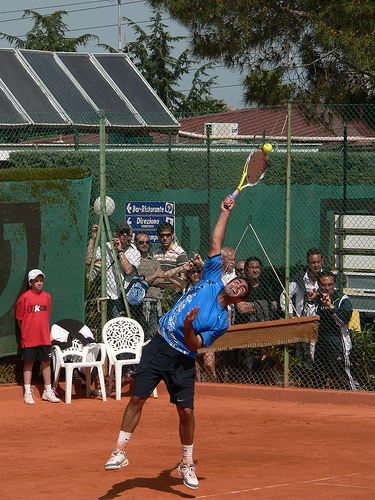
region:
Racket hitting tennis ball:
[257, 138, 277, 159]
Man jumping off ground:
[94, 429, 208, 499]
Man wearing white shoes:
[92, 434, 217, 490]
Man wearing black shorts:
[115, 326, 215, 416]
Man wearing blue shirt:
[154, 242, 236, 365]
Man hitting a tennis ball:
[149, 131, 284, 353]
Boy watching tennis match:
[14, 263, 71, 412]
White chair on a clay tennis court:
[98, 309, 166, 408]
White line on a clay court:
[268, 474, 330, 489]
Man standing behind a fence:
[300, 269, 358, 387]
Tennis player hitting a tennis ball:
[100, 139, 271, 486]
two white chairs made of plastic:
[45, 315, 153, 400]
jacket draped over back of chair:
[48, 315, 104, 401]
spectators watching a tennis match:
[85, 219, 350, 386]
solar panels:
[0, 46, 181, 125]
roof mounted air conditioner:
[201, 120, 236, 144]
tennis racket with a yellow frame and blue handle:
[220, 145, 265, 205]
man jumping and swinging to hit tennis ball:
[100, 188, 250, 488]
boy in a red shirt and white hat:
[11, 264, 56, 399]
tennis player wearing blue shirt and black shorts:
[101, 192, 251, 488]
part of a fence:
[334, 343, 346, 353]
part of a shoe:
[190, 467, 194, 472]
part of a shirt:
[182, 350, 185, 354]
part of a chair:
[91, 354, 111, 358]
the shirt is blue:
[144, 228, 236, 367]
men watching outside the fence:
[255, 229, 358, 390]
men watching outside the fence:
[157, 235, 297, 321]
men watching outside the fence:
[92, 220, 197, 351]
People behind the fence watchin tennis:
[84, 216, 356, 386]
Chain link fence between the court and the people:
[0, 97, 371, 390]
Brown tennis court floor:
[0, 370, 372, 494]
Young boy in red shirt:
[9, 261, 57, 402]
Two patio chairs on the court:
[46, 311, 157, 401]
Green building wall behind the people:
[0, 142, 369, 313]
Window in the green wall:
[316, 196, 372, 316]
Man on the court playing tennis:
[101, 194, 253, 490]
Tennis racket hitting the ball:
[220, 138, 274, 212]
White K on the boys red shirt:
[29, 301, 43, 314]